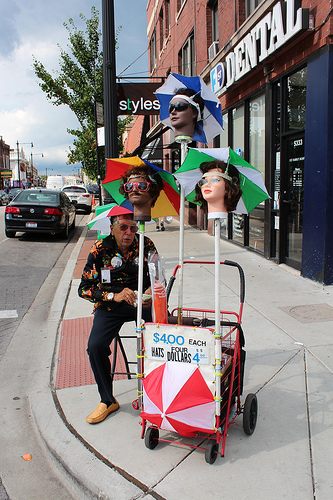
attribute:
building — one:
[131, 6, 332, 289]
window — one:
[276, 143, 309, 276]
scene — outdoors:
[4, 1, 331, 490]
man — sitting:
[66, 185, 188, 425]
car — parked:
[1, 176, 85, 256]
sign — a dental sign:
[218, 0, 310, 105]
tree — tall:
[55, 16, 118, 208]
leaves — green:
[38, 7, 119, 191]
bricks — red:
[127, 0, 326, 131]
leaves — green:
[44, 10, 134, 197]